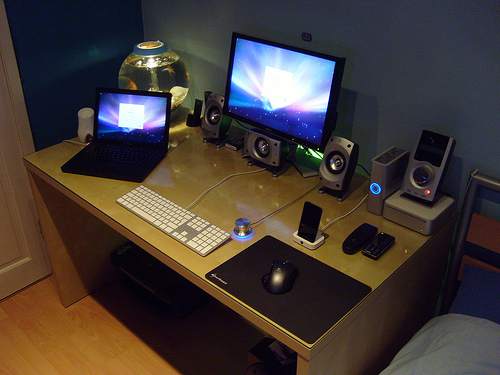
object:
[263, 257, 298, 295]
mouse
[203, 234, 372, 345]
mouse pad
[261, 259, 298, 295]
glare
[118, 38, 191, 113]
fish bowl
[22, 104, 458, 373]
desk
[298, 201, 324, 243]
ipod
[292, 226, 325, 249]
dock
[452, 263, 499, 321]
pillow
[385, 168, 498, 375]
bed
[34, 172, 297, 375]
shadow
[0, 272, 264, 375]
floor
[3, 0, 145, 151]
wall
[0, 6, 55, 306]
door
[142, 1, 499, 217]
wall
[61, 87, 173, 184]
laptop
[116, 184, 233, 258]
keyboard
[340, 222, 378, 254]
remote control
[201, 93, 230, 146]
speaker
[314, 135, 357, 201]
speaker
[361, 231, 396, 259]
cellphone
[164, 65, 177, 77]
fish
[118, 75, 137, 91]
fish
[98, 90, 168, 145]
laptop screen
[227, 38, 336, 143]
screen